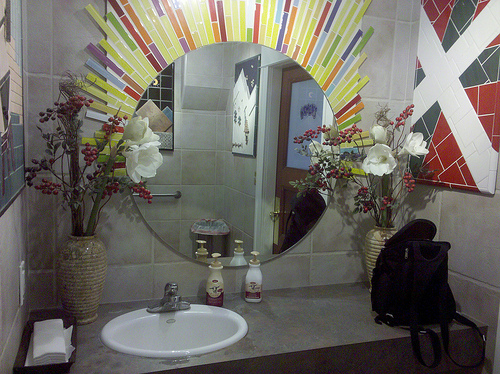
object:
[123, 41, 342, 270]
mirror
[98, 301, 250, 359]
sink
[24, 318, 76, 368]
paper towels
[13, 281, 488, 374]
counter top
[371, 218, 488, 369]
bag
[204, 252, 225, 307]
soap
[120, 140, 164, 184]
flower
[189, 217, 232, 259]
trash can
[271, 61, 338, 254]
door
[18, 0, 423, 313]
wall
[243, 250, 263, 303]
soap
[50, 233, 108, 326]
vase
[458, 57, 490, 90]
tile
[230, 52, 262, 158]
wall decoration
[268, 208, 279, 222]
door handle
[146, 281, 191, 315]
faucet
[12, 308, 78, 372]
rack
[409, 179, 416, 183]
cherry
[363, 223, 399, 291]
vase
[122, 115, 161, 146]
flower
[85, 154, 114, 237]
stem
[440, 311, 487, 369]
strap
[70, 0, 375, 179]
decoration